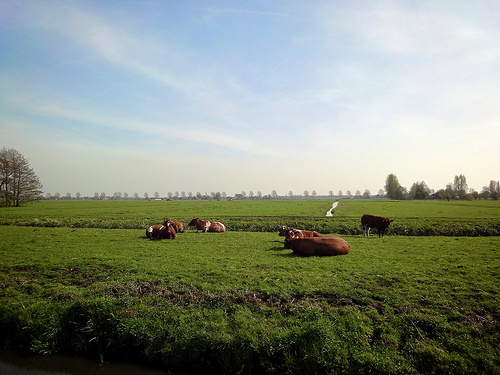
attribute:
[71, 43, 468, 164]
sky — white, beautiful 